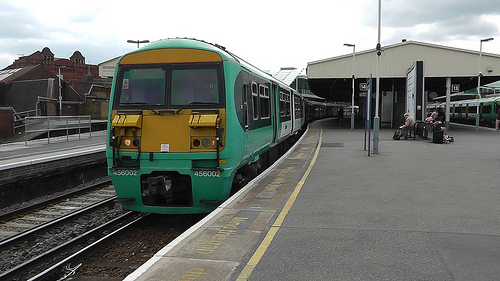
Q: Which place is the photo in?
A: It is at the train station.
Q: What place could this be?
A: It is a train station.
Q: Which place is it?
A: It is a train station.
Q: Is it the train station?
A: Yes, it is the train station.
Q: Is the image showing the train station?
A: Yes, it is showing the train station.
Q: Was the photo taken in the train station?
A: Yes, it was taken in the train station.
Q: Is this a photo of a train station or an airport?
A: It is showing a train station.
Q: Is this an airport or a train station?
A: It is a train station.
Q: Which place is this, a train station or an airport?
A: It is a train station.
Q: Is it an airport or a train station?
A: It is a train station.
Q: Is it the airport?
A: No, it is the train station.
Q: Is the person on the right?
A: Yes, the person is on the right of the image.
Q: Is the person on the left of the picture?
A: No, the person is on the right of the image.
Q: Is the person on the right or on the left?
A: The person is on the right of the image.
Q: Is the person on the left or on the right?
A: The person is on the right of the image.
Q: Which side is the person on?
A: The person is on the right of the image.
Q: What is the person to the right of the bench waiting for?
A: The person is waiting for the train.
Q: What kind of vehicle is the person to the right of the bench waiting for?
A: The person is waiting for the train.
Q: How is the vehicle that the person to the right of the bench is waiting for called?
A: The vehicle is a train.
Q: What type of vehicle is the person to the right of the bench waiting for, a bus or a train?
A: The person is waiting for a train.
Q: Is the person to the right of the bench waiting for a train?
A: Yes, the person is waiting for a train.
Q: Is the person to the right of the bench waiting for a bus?
A: No, the person is waiting for a train.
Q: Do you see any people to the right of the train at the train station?
A: Yes, there is a person to the right of the train.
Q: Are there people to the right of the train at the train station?
A: Yes, there is a person to the right of the train.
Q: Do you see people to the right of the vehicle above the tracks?
A: Yes, there is a person to the right of the train.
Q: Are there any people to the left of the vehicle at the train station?
A: No, the person is to the right of the train.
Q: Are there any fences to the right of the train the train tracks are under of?
A: No, there is a person to the right of the train.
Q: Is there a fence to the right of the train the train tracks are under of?
A: No, there is a person to the right of the train.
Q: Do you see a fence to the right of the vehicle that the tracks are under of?
A: No, there is a person to the right of the train.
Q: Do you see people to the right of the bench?
A: Yes, there is a person to the right of the bench.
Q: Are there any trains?
A: Yes, there is a train.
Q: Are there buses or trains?
A: Yes, there is a train.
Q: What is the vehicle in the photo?
A: The vehicle is a train.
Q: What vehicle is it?
A: The vehicle is a train.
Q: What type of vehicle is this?
A: This is a train.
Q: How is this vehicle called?
A: This is a train.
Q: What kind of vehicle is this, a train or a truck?
A: This is a train.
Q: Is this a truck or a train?
A: This is a train.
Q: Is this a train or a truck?
A: This is a train.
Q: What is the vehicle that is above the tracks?
A: The vehicle is a train.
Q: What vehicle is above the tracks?
A: The vehicle is a train.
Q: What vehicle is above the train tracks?
A: The vehicle is a train.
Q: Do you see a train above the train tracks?
A: Yes, there is a train above the train tracks.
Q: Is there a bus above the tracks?
A: No, there is a train above the tracks.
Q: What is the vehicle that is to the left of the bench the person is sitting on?
A: The vehicle is a train.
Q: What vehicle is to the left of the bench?
A: The vehicle is a train.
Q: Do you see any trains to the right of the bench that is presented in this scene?
A: No, the train is to the left of the bench.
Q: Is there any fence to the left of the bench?
A: No, there is a train to the left of the bench.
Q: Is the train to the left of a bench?
A: Yes, the train is to the left of a bench.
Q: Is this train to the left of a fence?
A: No, the train is to the left of a bench.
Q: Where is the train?
A: The train is at the train station.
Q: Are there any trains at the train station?
A: Yes, there is a train at the train station.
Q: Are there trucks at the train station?
A: No, there is a train at the train station.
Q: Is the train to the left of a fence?
A: No, the train is to the left of a person.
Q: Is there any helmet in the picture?
A: No, there are no helmets.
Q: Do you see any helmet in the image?
A: No, there are no helmets.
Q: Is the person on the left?
A: No, the person is on the right of the image.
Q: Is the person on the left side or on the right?
A: The person is on the right of the image.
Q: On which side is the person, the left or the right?
A: The person is on the right of the image.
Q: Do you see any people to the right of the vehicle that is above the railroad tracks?
A: Yes, there is a person to the right of the train.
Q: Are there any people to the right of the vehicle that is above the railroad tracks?
A: Yes, there is a person to the right of the train.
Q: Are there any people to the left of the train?
A: No, the person is to the right of the train.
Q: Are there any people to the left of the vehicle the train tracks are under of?
A: No, the person is to the right of the train.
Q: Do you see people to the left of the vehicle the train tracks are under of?
A: No, the person is to the right of the train.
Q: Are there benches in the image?
A: Yes, there is a bench.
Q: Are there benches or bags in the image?
A: Yes, there is a bench.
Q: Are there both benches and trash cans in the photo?
A: No, there is a bench but no trash cans.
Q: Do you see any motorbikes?
A: No, there are no motorbikes.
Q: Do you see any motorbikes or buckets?
A: No, there are no motorbikes or buckets.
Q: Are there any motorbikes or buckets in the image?
A: No, there are no motorbikes or buckets.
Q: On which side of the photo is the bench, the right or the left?
A: The bench is on the right of the image.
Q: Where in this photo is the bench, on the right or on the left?
A: The bench is on the right of the image.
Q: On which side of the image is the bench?
A: The bench is on the right of the image.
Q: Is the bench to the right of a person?
A: No, the bench is to the left of a person.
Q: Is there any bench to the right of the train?
A: Yes, there is a bench to the right of the train.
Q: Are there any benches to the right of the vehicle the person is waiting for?
A: Yes, there is a bench to the right of the train.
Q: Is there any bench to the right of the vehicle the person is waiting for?
A: Yes, there is a bench to the right of the train.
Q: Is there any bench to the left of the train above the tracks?
A: No, the bench is to the right of the train.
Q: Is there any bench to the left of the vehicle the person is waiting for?
A: No, the bench is to the right of the train.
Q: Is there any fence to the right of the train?
A: No, there is a bench to the right of the train.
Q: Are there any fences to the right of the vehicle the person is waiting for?
A: No, there is a bench to the right of the train.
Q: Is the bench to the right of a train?
A: Yes, the bench is to the right of a train.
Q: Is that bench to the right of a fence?
A: No, the bench is to the right of a train.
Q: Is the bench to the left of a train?
A: No, the bench is to the right of a train.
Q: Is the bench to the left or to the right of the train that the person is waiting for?
A: The bench is to the right of the train.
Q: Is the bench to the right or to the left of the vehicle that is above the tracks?
A: The bench is to the right of the train.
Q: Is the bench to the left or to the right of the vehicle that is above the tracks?
A: The bench is to the right of the train.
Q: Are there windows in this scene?
A: Yes, there are windows.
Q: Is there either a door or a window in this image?
A: Yes, there are windows.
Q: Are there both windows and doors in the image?
A: Yes, there are both windows and doors.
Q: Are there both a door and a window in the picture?
A: Yes, there are both a window and a door.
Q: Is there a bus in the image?
A: No, there are no buses.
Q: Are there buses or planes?
A: No, there are no buses or planes.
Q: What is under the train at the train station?
A: The tracks are under the train.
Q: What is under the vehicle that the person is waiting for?
A: The tracks are under the train.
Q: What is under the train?
A: The tracks are under the train.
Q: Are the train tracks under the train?
A: Yes, the train tracks are under the train.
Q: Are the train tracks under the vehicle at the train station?
A: Yes, the train tracks are under the train.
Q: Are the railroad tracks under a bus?
A: No, the railroad tracks are under the train.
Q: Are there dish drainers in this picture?
A: No, there are no dish drainers.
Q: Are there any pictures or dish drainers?
A: No, there are no dish drainers or pictures.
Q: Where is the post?
A: The post is at the train station.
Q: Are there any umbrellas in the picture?
A: No, there are no umbrellas.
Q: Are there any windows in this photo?
A: Yes, there is a window.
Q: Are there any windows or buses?
A: Yes, there is a window.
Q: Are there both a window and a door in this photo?
A: Yes, there are both a window and a door.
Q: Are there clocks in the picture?
A: No, there are no clocks.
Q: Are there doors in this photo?
A: Yes, there is a door.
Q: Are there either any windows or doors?
A: Yes, there is a door.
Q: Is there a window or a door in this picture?
A: Yes, there is a door.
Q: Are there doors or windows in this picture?
A: Yes, there is a door.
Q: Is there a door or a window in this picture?
A: Yes, there is a door.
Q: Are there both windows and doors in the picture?
A: Yes, there are both a door and a window.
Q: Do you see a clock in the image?
A: No, there are no clocks.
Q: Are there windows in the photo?
A: Yes, there is a window.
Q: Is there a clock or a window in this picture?
A: Yes, there is a window.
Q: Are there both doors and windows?
A: Yes, there are both a window and a door.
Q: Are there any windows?
A: Yes, there is a window.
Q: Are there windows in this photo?
A: Yes, there is a window.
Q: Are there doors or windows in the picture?
A: Yes, there is a window.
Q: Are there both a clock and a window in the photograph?
A: No, there is a window but no clocks.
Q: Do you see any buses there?
A: No, there are no buses.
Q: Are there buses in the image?
A: No, there are no buses.